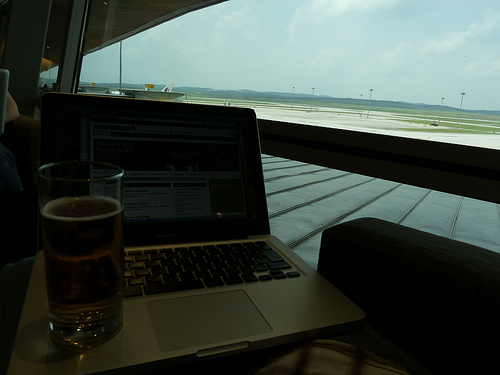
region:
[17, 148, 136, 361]
glass of beer sitting on a lap top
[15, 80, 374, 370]
small grey lap top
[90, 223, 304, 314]
black plastic key board keys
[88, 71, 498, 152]
view of air port run way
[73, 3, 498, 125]
cloudy grey sky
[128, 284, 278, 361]
matte grey mouse touch pad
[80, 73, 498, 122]
distant mountains on the horizon line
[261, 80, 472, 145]
many tall lights on poles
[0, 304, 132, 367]
light refracting through glass of beer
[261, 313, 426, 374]
plaid printed material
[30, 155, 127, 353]
A glass sitting on a computer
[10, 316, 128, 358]
Shadows from the glass on the computer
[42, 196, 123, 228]
The froth of the beer in the glass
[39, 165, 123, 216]
The empty portion of the glass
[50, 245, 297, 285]
The black keys of a key board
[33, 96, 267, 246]
The screen of a computer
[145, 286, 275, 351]
The track pad of the computer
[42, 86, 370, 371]
A laptop on somebodies lap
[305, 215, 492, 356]
The arm of the chair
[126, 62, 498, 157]
The feild outside of the window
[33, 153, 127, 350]
Iced tea drink on the laptop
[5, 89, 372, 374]
Grey and black laptop on the chair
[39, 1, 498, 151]
Airport field in the background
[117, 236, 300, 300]
Black keys of the keyboard of the laptop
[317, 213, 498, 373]
Arm rest of the sofa next to a laptop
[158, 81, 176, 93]
white tail of an aircraft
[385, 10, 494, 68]
White cloud at the sky in the background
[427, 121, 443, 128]
Black vehicle at the airport in the background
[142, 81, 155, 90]
Gate terminal sign near the aircraft's tail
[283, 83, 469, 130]
Aircraft light poles in the airport field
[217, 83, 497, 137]
The feild outside of the window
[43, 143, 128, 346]
The glass sitting on the computer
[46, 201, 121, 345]
The beer sitting in the glass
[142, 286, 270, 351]
The track pad on the computer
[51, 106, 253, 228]
The screen on the computer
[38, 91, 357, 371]
A computer sitting in someones ;ap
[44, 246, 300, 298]
The keys on the keyboard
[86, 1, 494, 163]
The window looking out in the field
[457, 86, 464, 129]
The light pole in the distance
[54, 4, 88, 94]
The beam between the two windows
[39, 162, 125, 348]
glass of beer sitting on the edge of the laptop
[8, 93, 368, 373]
a laptop computer with a glass of beer on the edge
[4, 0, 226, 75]
section of the roof overhanging the area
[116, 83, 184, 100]
gray boat visible in the distance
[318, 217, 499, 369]
arm of the furniture next to the laptop computer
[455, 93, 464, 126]
one of the lamp posts in the distance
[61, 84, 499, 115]
dark hills visible on the horizon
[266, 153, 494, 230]
section of the flooring where the laptop is situated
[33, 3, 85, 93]
support beams holding the roof overhang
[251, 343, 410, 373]
seat of the furniture next to the laptop